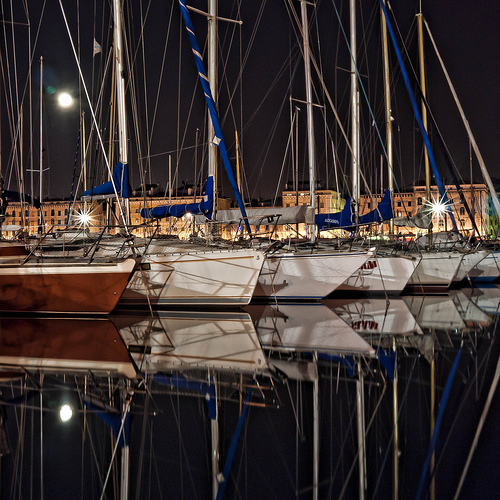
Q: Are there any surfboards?
A: No, there are no surfboards.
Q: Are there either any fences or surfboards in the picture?
A: No, there are no surfboards or fences.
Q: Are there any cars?
A: No, there are no cars.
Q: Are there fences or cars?
A: No, there are no cars or fences.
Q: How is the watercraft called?
A: The watercraft is boats.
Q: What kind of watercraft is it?
A: The watercraft is boats.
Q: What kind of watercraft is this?
A: These are boats.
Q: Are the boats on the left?
A: Yes, the boats are on the left of the image.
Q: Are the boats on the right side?
A: No, the boats are on the left of the image.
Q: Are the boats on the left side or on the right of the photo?
A: The boats are on the left of the image.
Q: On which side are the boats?
A: The boats are on the left of the image.